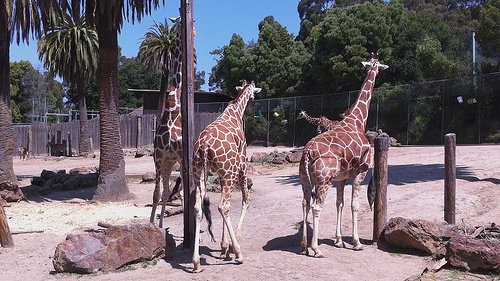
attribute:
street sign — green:
[248, 105, 273, 121]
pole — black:
[255, 107, 279, 151]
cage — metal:
[9, 56, 499, 279]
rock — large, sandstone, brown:
[38, 193, 190, 279]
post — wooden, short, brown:
[364, 123, 397, 246]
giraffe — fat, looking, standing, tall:
[284, 46, 393, 257]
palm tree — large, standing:
[64, 3, 147, 217]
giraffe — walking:
[284, 99, 343, 136]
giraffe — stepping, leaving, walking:
[194, 60, 269, 266]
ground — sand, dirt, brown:
[7, 147, 497, 277]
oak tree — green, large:
[302, 3, 468, 132]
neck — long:
[347, 72, 388, 126]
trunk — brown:
[95, 23, 145, 198]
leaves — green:
[22, 0, 106, 84]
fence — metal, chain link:
[201, 72, 499, 140]